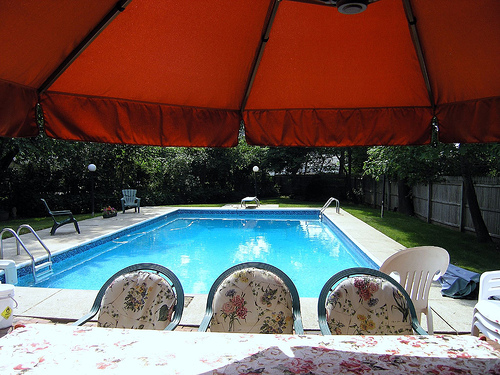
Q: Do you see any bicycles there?
A: No, there are no bicycles.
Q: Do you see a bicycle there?
A: No, there are no bicycles.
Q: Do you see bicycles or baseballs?
A: No, there are no bicycles or baseballs.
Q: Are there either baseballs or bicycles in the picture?
A: No, there are no bicycles or baseballs.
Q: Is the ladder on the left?
A: Yes, the ladder is on the left of the image.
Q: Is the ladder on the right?
A: No, the ladder is on the left of the image.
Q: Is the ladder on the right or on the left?
A: The ladder is on the left of the image.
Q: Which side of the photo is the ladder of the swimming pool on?
A: The ladder is on the left of the image.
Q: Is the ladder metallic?
A: Yes, the ladder is metallic.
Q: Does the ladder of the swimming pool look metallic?
A: Yes, the ladder is metallic.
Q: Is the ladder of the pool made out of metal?
A: Yes, the ladder is made of metal.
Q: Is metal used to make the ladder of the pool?
A: Yes, the ladder is made of metal.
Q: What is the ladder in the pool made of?
A: The ladder is made of metal.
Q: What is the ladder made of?
A: The ladder is made of metal.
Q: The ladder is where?
A: The ladder is in the pool.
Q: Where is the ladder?
A: The ladder is in the pool.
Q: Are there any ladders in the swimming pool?
A: Yes, there is a ladder in the swimming pool.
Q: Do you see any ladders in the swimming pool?
A: Yes, there is a ladder in the swimming pool.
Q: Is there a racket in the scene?
A: No, there are no rackets.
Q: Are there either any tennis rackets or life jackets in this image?
A: No, there are no tennis rackets or life jackets.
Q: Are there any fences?
A: Yes, there is a fence.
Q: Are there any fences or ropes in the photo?
A: Yes, there is a fence.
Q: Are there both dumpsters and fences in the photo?
A: No, there is a fence but no dumpsters.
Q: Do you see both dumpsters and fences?
A: No, there is a fence but no dumpsters.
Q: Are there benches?
A: No, there are no benches.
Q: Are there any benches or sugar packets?
A: No, there are no benches or sugar packets.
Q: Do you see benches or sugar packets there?
A: No, there are no benches or sugar packets.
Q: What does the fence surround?
A: The fence surrounds the pool.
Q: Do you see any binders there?
A: No, there are no binders.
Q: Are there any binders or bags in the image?
A: No, there are no binders or bags.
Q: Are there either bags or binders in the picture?
A: No, there are no binders or bags.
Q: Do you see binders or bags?
A: No, there are no binders or bags.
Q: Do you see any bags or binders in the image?
A: No, there are no binders or bags.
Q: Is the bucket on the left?
A: Yes, the bucket is on the left of the image.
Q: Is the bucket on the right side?
A: No, the bucket is on the left of the image.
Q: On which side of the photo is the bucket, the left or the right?
A: The bucket is on the left of the image.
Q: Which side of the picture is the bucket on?
A: The bucket is on the left of the image.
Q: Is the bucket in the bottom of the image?
A: Yes, the bucket is in the bottom of the image.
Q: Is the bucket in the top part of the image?
A: No, the bucket is in the bottom of the image.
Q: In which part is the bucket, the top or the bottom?
A: The bucket is in the bottom of the image.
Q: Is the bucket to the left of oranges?
A: No, the bucket is to the left of the chairs.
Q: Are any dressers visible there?
A: No, there are no dressers.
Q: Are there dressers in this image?
A: No, there are no dressers.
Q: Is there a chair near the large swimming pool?
A: Yes, there are chairs near the swimming pool.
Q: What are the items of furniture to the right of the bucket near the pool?
A: The pieces of furniture are chairs.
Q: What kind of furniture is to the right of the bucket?
A: The pieces of furniture are chairs.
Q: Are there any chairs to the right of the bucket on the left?
A: Yes, there are chairs to the right of the bucket.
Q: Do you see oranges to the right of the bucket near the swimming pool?
A: No, there are chairs to the right of the bucket.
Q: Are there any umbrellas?
A: Yes, there is an umbrella.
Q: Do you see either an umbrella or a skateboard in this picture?
A: Yes, there is an umbrella.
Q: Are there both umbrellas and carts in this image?
A: No, there is an umbrella but no carts.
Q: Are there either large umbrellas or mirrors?
A: Yes, there is a large umbrella.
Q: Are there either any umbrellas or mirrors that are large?
A: Yes, the umbrella is large.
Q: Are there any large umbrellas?
A: Yes, there is a large umbrella.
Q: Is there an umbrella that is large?
A: Yes, there is an umbrella that is large.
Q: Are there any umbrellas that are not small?
A: Yes, there is a large umbrella.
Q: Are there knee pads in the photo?
A: No, there are no knee pads.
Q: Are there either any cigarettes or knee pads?
A: No, there are no knee pads or cigarettes.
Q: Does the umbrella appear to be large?
A: Yes, the umbrella is large.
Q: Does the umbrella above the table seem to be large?
A: Yes, the umbrella is large.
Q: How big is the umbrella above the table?
A: The umbrella is large.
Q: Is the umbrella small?
A: No, the umbrella is large.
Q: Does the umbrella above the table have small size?
A: No, the umbrella is large.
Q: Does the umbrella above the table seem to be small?
A: No, the umbrella is large.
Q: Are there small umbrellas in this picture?
A: No, there is an umbrella but it is large.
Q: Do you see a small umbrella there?
A: No, there is an umbrella but it is large.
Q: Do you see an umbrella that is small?
A: No, there is an umbrella but it is large.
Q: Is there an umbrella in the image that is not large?
A: No, there is an umbrella but it is large.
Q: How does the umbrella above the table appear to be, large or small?
A: The umbrella is large.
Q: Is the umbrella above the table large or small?
A: The umbrella is large.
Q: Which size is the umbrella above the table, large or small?
A: The umbrella is large.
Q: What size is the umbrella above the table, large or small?
A: The umbrella is large.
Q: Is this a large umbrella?
A: Yes, this is a large umbrella.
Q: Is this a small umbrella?
A: No, this is a large umbrella.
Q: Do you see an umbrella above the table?
A: Yes, there is an umbrella above the table.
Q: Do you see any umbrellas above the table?
A: Yes, there is an umbrella above the table.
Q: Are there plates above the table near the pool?
A: No, there is an umbrella above the table.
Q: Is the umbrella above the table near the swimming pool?
A: Yes, the umbrella is above the table.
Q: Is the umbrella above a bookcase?
A: No, the umbrella is above the table.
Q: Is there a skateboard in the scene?
A: No, there are no skateboards.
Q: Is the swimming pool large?
A: Yes, the swimming pool is large.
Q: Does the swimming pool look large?
A: Yes, the swimming pool is large.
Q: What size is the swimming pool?
A: The swimming pool is large.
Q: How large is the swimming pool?
A: The swimming pool is large.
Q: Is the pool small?
A: No, the pool is large.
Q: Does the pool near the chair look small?
A: No, the swimming pool is large.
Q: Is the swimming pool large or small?
A: The swimming pool is large.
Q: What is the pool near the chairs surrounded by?
A: The pool is surrounded by the fence.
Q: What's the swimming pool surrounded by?
A: The pool is surrounded by the fence.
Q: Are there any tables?
A: Yes, there is a table.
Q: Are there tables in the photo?
A: Yes, there is a table.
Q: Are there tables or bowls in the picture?
A: Yes, there is a table.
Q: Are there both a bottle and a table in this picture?
A: No, there is a table but no bottles.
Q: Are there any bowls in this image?
A: No, there are no bowls.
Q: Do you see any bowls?
A: No, there are no bowls.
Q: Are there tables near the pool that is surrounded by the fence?
A: Yes, there is a table near the pool.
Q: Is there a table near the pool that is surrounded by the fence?
A: Yes, there is a table near the pool.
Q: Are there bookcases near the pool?
A: No, there is a table near the pool.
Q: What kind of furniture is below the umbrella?
A: The piece of furniture is a table.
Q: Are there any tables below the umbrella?
A: Yes, there is a table below the umbrella.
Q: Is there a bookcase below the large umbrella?
A: No, there is a table below the umbrella.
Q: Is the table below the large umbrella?
A: Yes, the table is below the umbrella.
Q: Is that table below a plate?
A: No, the table is below the umbrella.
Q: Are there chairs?
A: Yes, there is a chair.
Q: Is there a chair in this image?
A: Yes, there is a chair.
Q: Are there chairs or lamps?
A: Yes, there is a chair.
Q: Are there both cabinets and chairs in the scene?
A: No, there is a chair but no cabinets.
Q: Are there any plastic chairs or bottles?
A: Yes, there is a plastic chair.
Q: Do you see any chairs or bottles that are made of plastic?
A: Yes, the chair is made of plastic.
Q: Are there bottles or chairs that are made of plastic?
A: Yes, the chair is made of plastic.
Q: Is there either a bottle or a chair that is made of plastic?
A: Yes, the chair is made of plastic.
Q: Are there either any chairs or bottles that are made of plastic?
A: Yes, the chair is made of plastic.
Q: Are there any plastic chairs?
A: Yes, there is a chair that is made of plastic.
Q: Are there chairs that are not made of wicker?
A: Yes, there is a chair that is made of plastic.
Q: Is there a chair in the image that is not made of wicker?
A: Yes, there is a chair that is made of plastic.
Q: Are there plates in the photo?
A: No, there are no plates.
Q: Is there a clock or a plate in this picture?
A: No, there are no plates or clocks.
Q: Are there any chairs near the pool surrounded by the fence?
A: Yes, there is a chair near the pool.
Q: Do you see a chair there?
A: Yes, there is a chair.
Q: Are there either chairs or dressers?
A: Yes, there is a chair.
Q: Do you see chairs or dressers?
A: Yes, there is a chair.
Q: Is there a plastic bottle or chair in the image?
A: Yes, there is a plastic chair.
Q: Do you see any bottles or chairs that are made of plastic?
A: Yes, the chair is made of plastic.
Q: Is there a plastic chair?
A: Yes, there is a chair that is made of plastic.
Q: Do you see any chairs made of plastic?
A: Yes, there is a chair that is made of plastic.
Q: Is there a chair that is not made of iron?
A: Yes, there is a chair that is made of plastic.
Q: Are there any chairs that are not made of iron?
A: Yes, there is a chair that is made of plastic.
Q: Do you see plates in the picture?
A: No, there are no plates.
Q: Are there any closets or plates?
A: No, there are no plates or closets.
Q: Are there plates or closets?
A: No, there are no plates or closets.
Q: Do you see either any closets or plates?
A: No, there are no plates or closets.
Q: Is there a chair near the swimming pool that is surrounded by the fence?
A: Yes, there is a chair near the swimming pool.